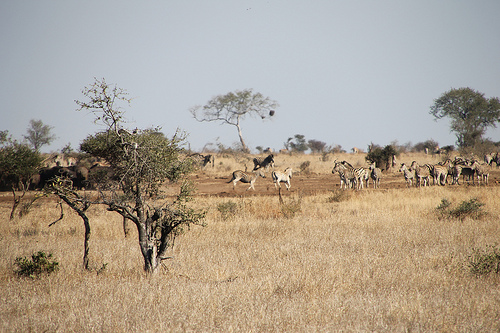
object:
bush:
[431, 195, 493, 222]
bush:
[464, 244, 500, 278]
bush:
[10, 249, 61, 281]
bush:
[326, 188, 353, 204]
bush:
[274, 197, 303, 219]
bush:
[216, 199, 242, 221]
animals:
[271, 165, 294, 191]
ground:
[2, 151, 498, 332]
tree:
[187, 86, 280, 152]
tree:
[428, 85, 500, 148]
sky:
[0, 0, 500, 155]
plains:
[0, 1, 496, 333]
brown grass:
[0, 148, 500, 331]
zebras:
[366, 161, 382, 189]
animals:
[57, 165, 90, 190]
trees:
[77, 125, 212, 276]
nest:
[125, 140, 140, 148]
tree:
[74, 124, 212, 273]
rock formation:
[42, 154, 77, 168]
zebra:
[225, 165, 267, 191]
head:
[258, 166, 267, 179]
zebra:
[271, 166, 295, 187]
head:
[286, 166, 294, 179]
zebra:
[331, 159, 359, 191]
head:
[332, 161, 341, 174]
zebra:
[397, 162, 415, 188]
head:
[398, 162, 406, 172]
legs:
[232, 177, 241, 190]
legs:
[277, 180, 282, 190]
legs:
[339, 179, 344, 189]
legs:
[419, 176, 423, 188]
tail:
[225, 172, 237, 184]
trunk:
[236, 125, 247, 150]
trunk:
[134, 224, 169, 274]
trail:
[2, 172, 500, 198]